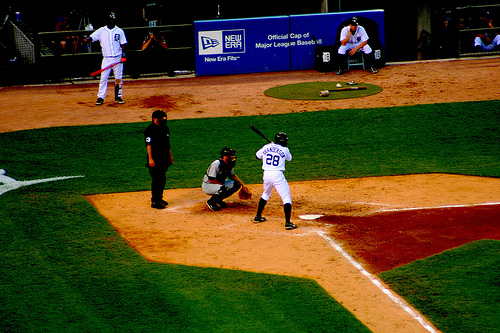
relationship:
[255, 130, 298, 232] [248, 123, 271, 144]
player holding bat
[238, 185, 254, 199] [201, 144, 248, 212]
mitt on catcher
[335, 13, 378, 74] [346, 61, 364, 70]
person sitting on chair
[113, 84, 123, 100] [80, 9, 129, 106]
brace on player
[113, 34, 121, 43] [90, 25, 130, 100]
logo on uniform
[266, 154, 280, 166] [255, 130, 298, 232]
number on player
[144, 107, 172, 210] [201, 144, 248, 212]
umpire behind catcher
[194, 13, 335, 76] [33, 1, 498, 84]
advertisement in front of dugout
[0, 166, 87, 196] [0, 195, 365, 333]
symbol in grass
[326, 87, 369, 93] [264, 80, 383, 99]
bat on deck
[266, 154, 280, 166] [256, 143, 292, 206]
number on uniform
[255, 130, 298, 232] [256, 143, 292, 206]
player in uniform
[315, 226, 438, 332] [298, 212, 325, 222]
chalk beside plate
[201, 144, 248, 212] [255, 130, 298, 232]
catcher behind player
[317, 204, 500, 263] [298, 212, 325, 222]
dirt beside plate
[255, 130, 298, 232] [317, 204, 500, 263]
player in dirt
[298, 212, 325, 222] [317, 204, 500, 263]
plate in dirt